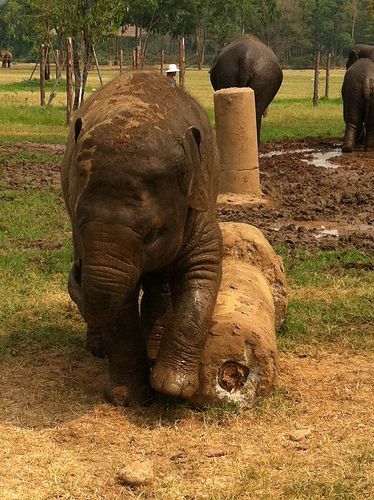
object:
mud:
[207, 137, 373, 257]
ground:
[0, 61, 373, 498]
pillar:
[211, 86, 268, 209]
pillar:
[188, 221, 288, 415]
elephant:
[58, 66, 224, 411]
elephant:
[206, 29, 283, 154]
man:
[162, 61, 179, 85]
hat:
[163, 62, 181, 75]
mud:
[47, 68, 143, 214]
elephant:
[0, 50, 13, 69]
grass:
[0, 63, 350, 171]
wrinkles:
[171, 246, 222, 283]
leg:
[158, 224, 222, 348]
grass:
[0, 176, 373, 500]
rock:
[115, 455, 159, 487]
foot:
[147, 350, 202, 401]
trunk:
[78, 234, 142, 359]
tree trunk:
[175, 28, 186, 92]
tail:
[235, 48, 255, 87]